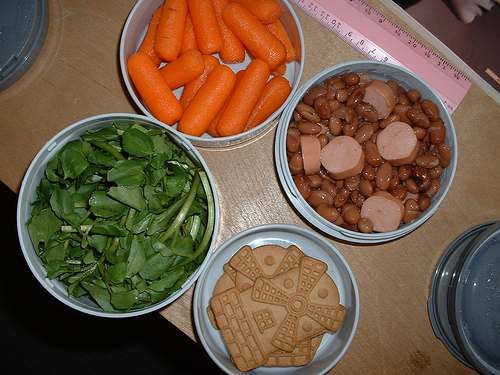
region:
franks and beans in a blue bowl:
[275, 60, 458, 245]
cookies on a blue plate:
[190, 222, 356, 372]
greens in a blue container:
[16, 110, 211, 315]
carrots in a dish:
[120, 0, 302, 147]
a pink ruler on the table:
[292, 0, 467, 116]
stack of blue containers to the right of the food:
[425, 216, 495, 371]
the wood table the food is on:
[0, 0, 497, 370]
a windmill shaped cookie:
[210, 255, 341, 366]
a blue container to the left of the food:
[0, 0, 47, 90]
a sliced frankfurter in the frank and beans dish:
[375, 120, 420, 165]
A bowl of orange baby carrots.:
[117, 1, 305, 150]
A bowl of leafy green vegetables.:
[17, 112, 217, 317]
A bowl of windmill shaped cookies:
[191, 223, 360, 373]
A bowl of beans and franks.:
[273, 59, 458, 241]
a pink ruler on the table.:
[293, 0, 473, 116]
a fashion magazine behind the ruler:
[384, 0, 499, 102]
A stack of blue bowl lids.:
[426, 220, 499, 374]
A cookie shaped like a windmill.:
[212, 256, 345, 368]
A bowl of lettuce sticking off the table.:
[16, 113, 219, 318]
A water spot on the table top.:
[408, 348, 430, 367]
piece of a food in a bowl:
[373, 119, 421, 166]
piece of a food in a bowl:
[216, 53, 272, 140]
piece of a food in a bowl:
[174, 60, 240, 139]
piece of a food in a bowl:
[123, 46, 185, 126]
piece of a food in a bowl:
[205, 253, 363, 373]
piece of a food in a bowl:
[245, 73, 292, 139]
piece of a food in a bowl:
[160, 50, 215, 92]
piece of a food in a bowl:
[295, 130, 323, 175]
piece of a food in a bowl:
[355, 95, 379, 125]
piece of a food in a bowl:
[333, 85, 350, 104]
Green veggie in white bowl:
[18, 114, 206, 300]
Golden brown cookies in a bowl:
[184, 214, 369, 374]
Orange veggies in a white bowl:
[86, 1, 311, 121]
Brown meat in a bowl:
[371, 119, 424, 170]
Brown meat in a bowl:
[318, 129, 371, 186]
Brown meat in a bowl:
[295, 125, 322, 180]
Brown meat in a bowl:
[351, 181, 423, 233]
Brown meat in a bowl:
[352, 77, 406, 110]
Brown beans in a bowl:
[297, 51, 485, 272]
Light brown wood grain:
[369, 265, 399, 323]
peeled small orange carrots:
[116, 3, 315, 160]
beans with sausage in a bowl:
[294, 65, 475, 295]